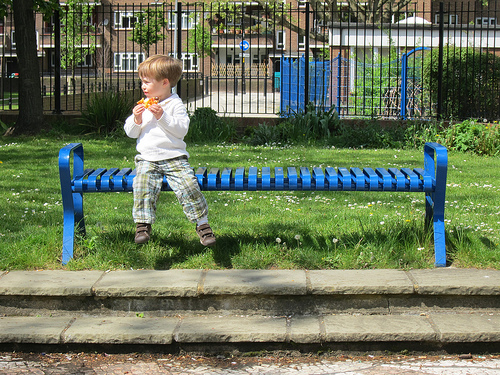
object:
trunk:
[9, 0, 43, 131]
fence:
[0, 0, 496, 120]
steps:
[0, 268, 500, 313]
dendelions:
[264, 225, 350, 251]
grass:
[0, 114, 500, 272]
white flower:
[294, 233, 302, 250]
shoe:
[195, 226, 218, 250]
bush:
[413, 36, 498, 125]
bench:
[55, 138, 449, 270]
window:
[167, 53, 201, 73]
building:
[0, 2, 496, 121]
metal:
[252, 167, 327, 193]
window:
[106, 50, 148, 73]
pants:
[127, 156, 212, 233]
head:
[135, 53, 183, 98]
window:
[162, 9, 210, 37]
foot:
[195, 224, 217, 246]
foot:
[131, 222, 152, 245]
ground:
[0, 123, 498, 271]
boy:
[122, 50, 217, 247]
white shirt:
[122, 94, 190, 159]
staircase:
[2, 265, 497, 352]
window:
[110, 12, 139, 33]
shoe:
[133, 221, 150, 242]